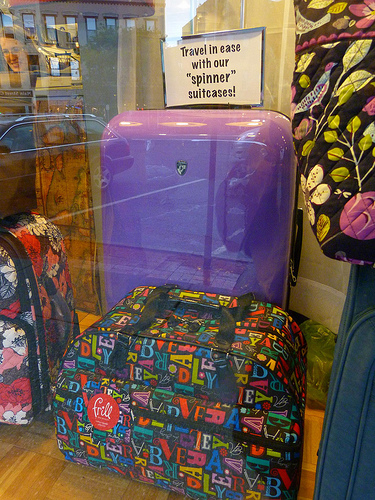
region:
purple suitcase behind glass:
[78, 93, 307, 330]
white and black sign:
[160, 27, 278, 112]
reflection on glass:
[67, 69, 268, 288]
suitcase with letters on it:
[57, 293, 318, 492]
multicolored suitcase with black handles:
[43, 284, 315, 493]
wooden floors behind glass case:
[7, 420, 279, 498]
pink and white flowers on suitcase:
[1, 212, 72, 432]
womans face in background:
[0, 28, 62, 82]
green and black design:
[301, 47, 374, 255]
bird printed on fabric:
[275, 52, 348, 129]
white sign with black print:
[158, 28, 259, 108]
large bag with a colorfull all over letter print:
[48, 284, 309, 499]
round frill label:
[82, 393, 120, 429]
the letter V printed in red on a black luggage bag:
[155, 437, 179, 461]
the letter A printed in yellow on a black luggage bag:
[170, 352, 196, 370]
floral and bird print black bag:
[291, 0, 370, 265]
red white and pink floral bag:
[0, 214, 77, 428]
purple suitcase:
[103, 108, 301, 304]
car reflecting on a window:
[2, 111, 133, 211]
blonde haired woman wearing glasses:
[1, 20, 55, 84]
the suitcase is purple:
[82, 68, 327, 362]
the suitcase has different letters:
[41, 257, 300, 499]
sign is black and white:
[137, 28, 271, 106]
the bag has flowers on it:
[294, 1, 372, 247]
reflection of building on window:
[0, 1, 189, 174]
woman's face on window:
[0, 22, 68, 113]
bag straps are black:
[106, 264, 291, 420]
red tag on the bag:
[78, 377, 137, 441]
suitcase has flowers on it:
[0, 190, 86, 448]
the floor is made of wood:
[2, 264, 357, 499]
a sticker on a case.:
[66, 380, 129, 446]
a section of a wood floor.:
[1, 417, 181, 498]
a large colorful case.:
[49, 284, 313, 497]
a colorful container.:
[3, 184, 83, 427]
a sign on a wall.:
[149, 14, 274, 121]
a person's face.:
[0, 17, 70, 89]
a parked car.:
[0, 59, 192, 202]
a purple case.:
[95, 98, 303, 324]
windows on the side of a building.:
[0, 13, 167, 54]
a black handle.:
[141, 290, 241, 329]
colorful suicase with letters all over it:
[57, 319, 297, 474]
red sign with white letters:
[77, 392, 128, 449]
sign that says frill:
[82, 394, 120, 440]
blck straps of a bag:
[133, 295, 250, 345]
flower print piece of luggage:
[0, 214, 57, 440]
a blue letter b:
[261, 475, 278, 498]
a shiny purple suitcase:
[103, 116, 284, 322]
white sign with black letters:
[165, 33, 252, 104]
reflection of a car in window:
[11, 103, 122, 193]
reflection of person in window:
[0, 24, 49, 64]